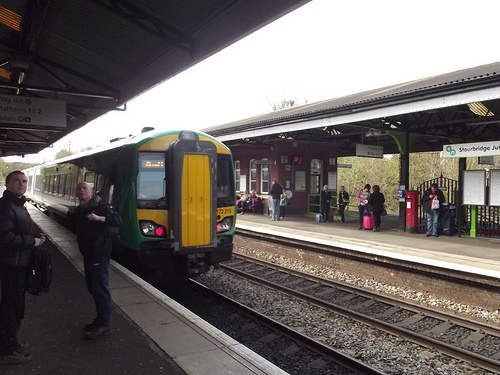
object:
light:
[140, 220, 161, 237]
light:
[220, 218, 235, 232]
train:
[11, 126, 242, 280]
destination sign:
[142, 160, 165, 168]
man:
[65, 179, 118, 342]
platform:
[1, 200, 268, 374]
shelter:
[199, 60, 500, 252]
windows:
[57, 173, 67, 195]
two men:
[1, 169, 123, 366]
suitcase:
[362, 214, 374, 232]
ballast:
[193, 245, 499, 374]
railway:
[185, 251, 496, 375]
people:
[334, 176, 352, 228]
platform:
[236, 203, 498, 281]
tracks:
[154, 226, 499, 373]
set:
[131, 284, 500, 374]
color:
[181, 152, 213, 248]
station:
[1, 0, 500, 372]